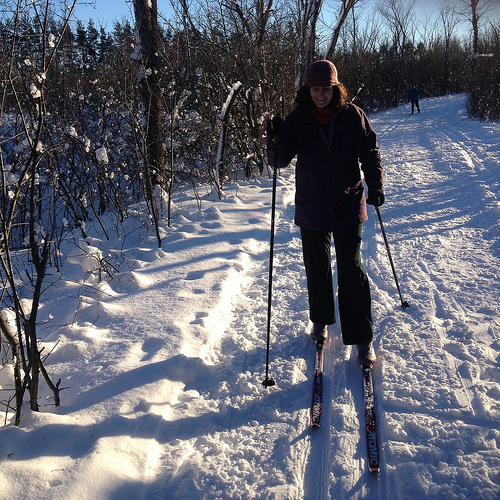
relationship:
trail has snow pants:
[264, 58, 384, 364] [289, 228, 381, 344]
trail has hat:
[264, 58, 384, 364] [301, 59, 345, 82]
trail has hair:
[264, 58, 384, 364] [278, 83, 350, 111]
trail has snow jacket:
[264, 58, 384, 364] [265, 109, 394, 230]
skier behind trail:
[394, 67, 429, 122] [264, 58, 384, 364]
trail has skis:
[264, 58, 384, 364] [300, 339, 382, 500]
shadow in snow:
[0, 92, 500, 500] [141, 248, 481, 484]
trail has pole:
[264, 58, 384, 364] [250, 147, 280, 407]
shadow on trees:
[0, 92, 500, 500] [54, 13, 267, 252]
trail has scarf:
[264, 58, 384, 364] [311, 107, 335, 126]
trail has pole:
[264, 58, 384, 364] [370, 188, 415, 318]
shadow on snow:
[62, 337, 306, 444] [141, 248, 481, 484]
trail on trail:
[264, 58, 384, 364] [207, 128, 498, 488]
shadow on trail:
[0, 92, 500, 500] [207, 128, 498, 488]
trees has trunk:
[54, 13, 267, 252] [130, 44, 172, 186]